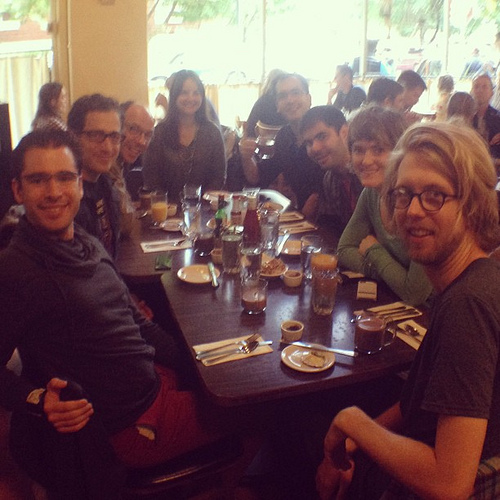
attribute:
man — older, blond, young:
[319, 105, 499, 499]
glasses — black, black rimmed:
[382, 179, 460, 214]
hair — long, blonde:
[378, 115, 491, 215]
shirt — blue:
[395, 256, 497, 440]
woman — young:
[324, 98, 437, 300]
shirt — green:
[333, 164, 440, 303]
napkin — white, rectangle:
[191, 325, 274, 372]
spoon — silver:
[200, 336, 262, 364]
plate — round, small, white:
[280, 333, 337, 372]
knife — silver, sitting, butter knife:
[271, 335, 361, 358]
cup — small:
[275, 318, 305, 341]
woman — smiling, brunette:
[140, 66, 229, 187]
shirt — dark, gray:
[139, 111, 233, 187]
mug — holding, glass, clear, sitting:
[234, 270, 280, 317]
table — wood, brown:
[118, 170, 441, 401]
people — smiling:
[4, 67, 496, 496]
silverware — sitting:
[195, 334, 264, 361]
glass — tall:
[253, 198, 283, 255]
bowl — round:
[161, 219, 187, 233]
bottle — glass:
[239, 196, 264, 246]